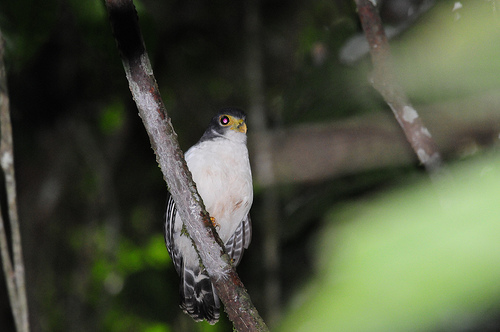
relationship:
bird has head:
[163, 106, 255, 326] [206, 108, 248, 144]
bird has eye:
[163, 106, 255, 326] [218, 115, 230, 126]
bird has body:
[163, 106, 255, 326] [166, 135, 252, 269]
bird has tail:
[163, 106, 255, 326] [175, 269, 223, 325]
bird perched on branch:
[163, 106, 255, 326] [104, 1, 269, 332]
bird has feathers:
[163, 106, 255, 326] [172, 138, 250, 277]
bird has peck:
[163, 106, 255, 326] [236, 121, 246, 135]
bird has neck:
[163, 106, 255, 326] [206, 125, 248, 143]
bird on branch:
[163, 106, 255, 326] [104, 1, 269, 332]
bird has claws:
[163, 106, 255, 326] [209, 216, 220, 230]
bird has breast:
[163, 106, 255, 326] [182, 138, 252, 205]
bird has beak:
[163, 106, 255, 326] [236, 121, 246, 135]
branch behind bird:
[244, 92, 498, 172] [163, 106, 255, 326]